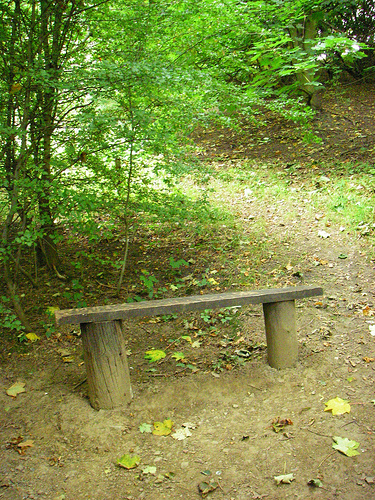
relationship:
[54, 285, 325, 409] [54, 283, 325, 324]
bench has seat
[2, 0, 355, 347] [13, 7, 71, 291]
tree has trunk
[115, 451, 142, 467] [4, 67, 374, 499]
leaf on ground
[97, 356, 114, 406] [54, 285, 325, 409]
crack in bench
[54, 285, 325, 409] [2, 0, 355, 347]
bench in front of tree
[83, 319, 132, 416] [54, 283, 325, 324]
log holding seat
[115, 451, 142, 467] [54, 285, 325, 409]
leaf under bench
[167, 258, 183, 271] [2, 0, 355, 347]
leaf on tree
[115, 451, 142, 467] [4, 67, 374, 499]
leaf strewn on ground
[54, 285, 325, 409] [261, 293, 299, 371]
bench has log